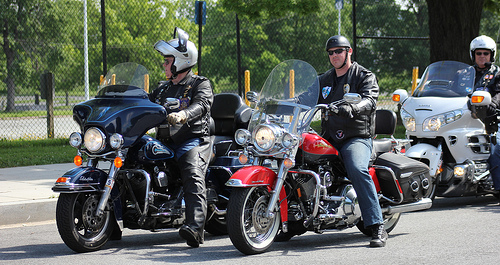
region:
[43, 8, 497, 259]
Three motorcyclists in the road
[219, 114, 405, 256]
Motorcycle is red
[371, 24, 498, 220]
Motorcycle is white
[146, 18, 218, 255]
Motorcyclist wears black outfit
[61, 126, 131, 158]
Three lights in front of motorcycle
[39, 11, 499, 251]
Motorcyclists travels to left direction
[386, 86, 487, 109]
Orange lights in front of motorcyclist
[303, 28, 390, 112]
Man has sun glasses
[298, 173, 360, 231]
Engine of motorcycle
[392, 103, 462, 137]
Headlights of motorcycle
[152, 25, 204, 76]
motorcycle helmet with visor up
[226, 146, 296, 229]
red motorcycle fender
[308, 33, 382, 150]
man riding motorcycle with helmet and leather vest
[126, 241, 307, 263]
shadow on pavement of motorcycle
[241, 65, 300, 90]
yellow cement pillars behind chain link fence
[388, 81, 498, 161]
large white motorcycle with yellow blinkers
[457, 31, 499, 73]
man with sunglasses and white helmet with microphone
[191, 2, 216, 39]
blue parking sign behind chain link fence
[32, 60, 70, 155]
wooden sign post with sign on it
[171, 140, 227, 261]
leather chaps on man riding motorcycles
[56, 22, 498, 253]
men riding motorcycles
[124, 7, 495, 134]
the men are wearing helmets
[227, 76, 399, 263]
the motorcycle is red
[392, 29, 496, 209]
the motorcycle is white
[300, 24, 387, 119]
the guy is wearing a black helmet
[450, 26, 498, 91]
the helmet is white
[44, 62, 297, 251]
the motorcycle is black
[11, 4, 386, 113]
the trees are green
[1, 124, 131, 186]
the grass is green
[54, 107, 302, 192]
the motorcycles have headlights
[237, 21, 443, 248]
man riding a red motorcycle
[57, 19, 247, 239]
man riding a black motorcycle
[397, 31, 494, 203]
man riding a white motorcycle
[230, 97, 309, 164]
light on motorcycle is on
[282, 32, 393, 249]
man wearing a black helmet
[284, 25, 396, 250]
man wearing dark sunglasses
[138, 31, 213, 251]
man wearing leather chaps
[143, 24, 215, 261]
man wearing gray helmet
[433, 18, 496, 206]
man wearing white helmet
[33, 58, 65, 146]
sign at the park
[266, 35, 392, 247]
Man wearing black helmet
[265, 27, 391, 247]
Man riding on red motorcycle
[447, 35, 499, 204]
Man wearing white helmet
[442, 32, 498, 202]
Man riding on white motorcycle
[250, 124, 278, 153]
Front middle light on red motorcycle is on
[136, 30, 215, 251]
Man wearing gray helmet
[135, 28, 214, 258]
Man riding blue motorcycle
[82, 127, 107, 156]
Front middle light on blue motorcycle is on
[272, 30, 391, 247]
Man on red motorcycle wearing black shoes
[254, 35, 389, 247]
Man on red motorcycle wearing black sunglasses